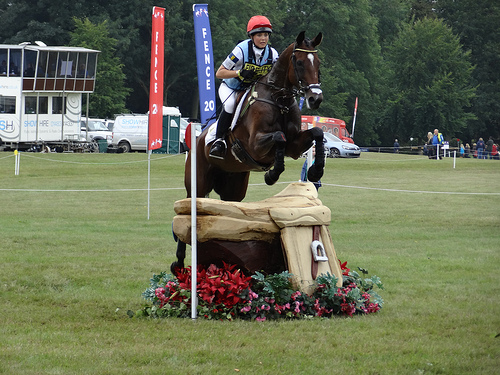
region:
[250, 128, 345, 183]
Horse feet in the middle of a vault jump.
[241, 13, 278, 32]
The red helmet of the female horse rider.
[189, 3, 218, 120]
A blue horse 20 sign.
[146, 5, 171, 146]
A red fence 20 sign.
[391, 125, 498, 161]
A group of people watching the woman and the horse.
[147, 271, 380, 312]
A set of beautiful flowers on the grass.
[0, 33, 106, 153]
A white spectator building.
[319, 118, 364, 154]
A white car and a red SUV.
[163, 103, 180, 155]
A green porta potty.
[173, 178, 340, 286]
The wood complex being vaulted over by a horse.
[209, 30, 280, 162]
Woman on horse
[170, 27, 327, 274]
Brown horse jumping over rocks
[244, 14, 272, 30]
Helmet is red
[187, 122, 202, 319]
Pole next to rock is white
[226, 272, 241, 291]
Red flower by rock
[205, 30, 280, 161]
Woman wearing blue vest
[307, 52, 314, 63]
White marking on brown horse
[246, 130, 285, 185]
Leg of horse up in the air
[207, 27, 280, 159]
Woman wearing white pants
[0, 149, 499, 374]
Grass is green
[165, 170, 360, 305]
a large rock shaped like a saddle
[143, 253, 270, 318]
red and pink flowers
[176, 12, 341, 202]
a young person jumping a horse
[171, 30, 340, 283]
a dark brown horse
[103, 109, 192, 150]
a white van behind an outhouse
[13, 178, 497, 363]
a green field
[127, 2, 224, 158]
two flags on the field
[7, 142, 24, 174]
a yellow flag on a white pole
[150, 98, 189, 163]
a green outhouse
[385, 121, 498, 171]
a group of people by the trees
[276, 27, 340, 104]
face of brown horse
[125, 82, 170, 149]
signs for horse racing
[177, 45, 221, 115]
blue fencing sign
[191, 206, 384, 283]
obstacle that horse jumps over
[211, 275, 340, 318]
flowers at base of hurdle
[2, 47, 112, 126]
trailer where commentators are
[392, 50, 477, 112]
large trees in background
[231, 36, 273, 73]
horse jockey outfit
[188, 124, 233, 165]
footing of jockey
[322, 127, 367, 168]
sedan car in background on the grass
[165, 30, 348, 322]
the horse is jumping a wood jump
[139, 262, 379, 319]
flowers and greenery surround the jump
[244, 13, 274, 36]
the rider has a helmet for protection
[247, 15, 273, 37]
the helmet is red on the horseback rider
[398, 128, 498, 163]
spectators are behind a fence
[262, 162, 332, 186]
the hose has hooves and horseshoes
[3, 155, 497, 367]
the grass is green around the jump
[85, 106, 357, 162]
vehicles are parked near the field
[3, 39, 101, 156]
an observation building is at the side of the field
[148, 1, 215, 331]
a red and blue flags marks the jump